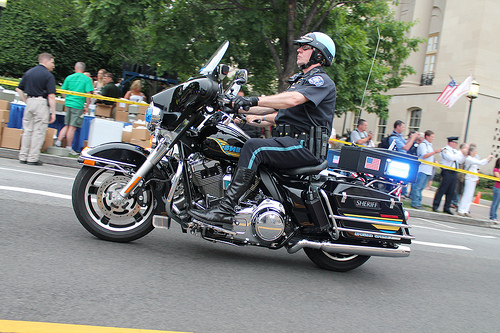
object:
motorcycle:
[68, 39, 423, 273]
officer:
[183, 27, 343, 231]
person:
[410, 129, 443, 210]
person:
[386, 118, 420, 154]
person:
[351, 118, 376, 147]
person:
[455, 147, 492, 219]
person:
[54, 61, 95, 156]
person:
[93, 72, 122, 111]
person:
[93, 69, 106, 88]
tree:
[78, 0, 172, 74]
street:
[0, 156, 500, 332]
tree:
[213, 0, 427, 117]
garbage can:
[337, 145, 391, 176]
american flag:
[332, 155, 341, 165]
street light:
[465, 80, 481, 100]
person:
[431, 135, 469, 216]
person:
[450, 142, 469, 209]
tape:
[0, 79, 150, 108]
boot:
[187, 165, 259, 231]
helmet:
[292, 31, 336, 67]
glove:
[233, 95, 259, 112]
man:
[14, 52, 57, 166]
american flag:
[436, 78, 469, 111]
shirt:
[60, 72, 95, 110]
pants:
[456, 175, 479, 214]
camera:
[489, 151, 499, 158]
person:
[487, 157, 499, 220]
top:
[492, 166, 499, 189]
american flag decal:
[363, 155, 382, 171]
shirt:
[15, 64, 56, 99]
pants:
[17, 96, 52, 163]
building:
[328, 0, 500, 177]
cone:
[472, 190, 482, 204]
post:
[463, 98, 473, 143]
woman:
[123, 79, 147, 102]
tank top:
[129, 91, 144, 102]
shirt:
[388, 130, 407, 154]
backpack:
[378, 133, 398, 149]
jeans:
[488, 186, 500, 220]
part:
[290, 35, 312, 49]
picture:
[0, 0, 499, 333]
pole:
[449, 75, 470, 102]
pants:
[237, 134, 327, 174]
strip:
[246, 138, 305, 170]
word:
[356, 199, 379, 208]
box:
[1, 127, 25, 150]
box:
[45, 128, 58, 147]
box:
[0, 109, 10, 122]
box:
[94, 103, 114, 117]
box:
[0, 99, 11, 110]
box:
[86, 117, 124, 147]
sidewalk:
[401, 195, 495, 228]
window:
[420, 53, 437, 86]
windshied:
[199, 39, 230, 76]